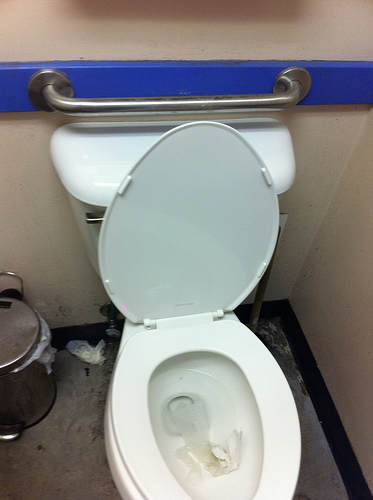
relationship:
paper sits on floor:
[63, 338, 108, 368] [1, 317, 354, 497]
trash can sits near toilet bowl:
[1, 268, 60, 444] [54, 107, 316, 499]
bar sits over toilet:
[62, 80, 341, 111] [96, 145, 310, 483]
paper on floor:
[67, 332, 114, 371] [1, 317, 354, 497]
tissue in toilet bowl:
[161, 394, 240, 477] [124, 326, 286, 496]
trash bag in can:
[19, 304, 55, 383] [1, 258, 50, 376]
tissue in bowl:
[161, 394, 240, 477] [142, 347, 273, 495]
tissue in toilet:
[161, 394, 240, 477] [103, 313, 302, 496]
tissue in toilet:
[161, 394, 240, 477] [43, 80, 370, 496]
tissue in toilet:
[161, 394, 240, 477] [48, 114, 304, 497]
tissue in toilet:
[190, 435, 240, 477] [89, 296, 318, 499]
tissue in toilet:
[161, 394, 240, 477] [55, 106, 343, 497]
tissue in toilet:
[161, 394, 240, 477] [24, 116, 355, 499]